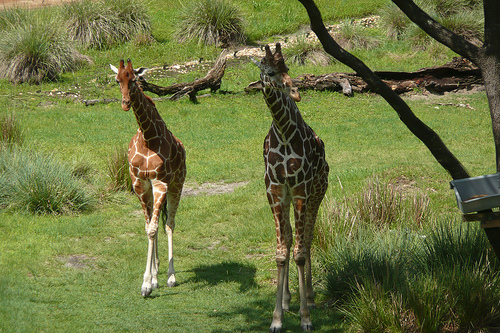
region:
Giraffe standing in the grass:
[90, 53, 213, 303]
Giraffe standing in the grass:
[244, 33, 371, 305]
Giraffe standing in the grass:
[66, 36, 370, 324]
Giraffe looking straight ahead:
[260, 51, 334, 138]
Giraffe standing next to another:
[86, 46, 203, 301]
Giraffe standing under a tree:
[241, 45, 343, 287]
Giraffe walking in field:
[90, 47, 200, 292]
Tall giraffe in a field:
[98, 43, 210, 310]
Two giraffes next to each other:
[90, 54, 347, 274]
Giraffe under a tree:
[239, 34, 371, 294]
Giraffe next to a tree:
[239, 36, 360, 330]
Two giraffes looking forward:
[96, 45, 383, 181]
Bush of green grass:
[13, 116, 90, 228]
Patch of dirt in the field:
[188, 138, 253, 208]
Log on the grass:
[156, 59, 238, 95]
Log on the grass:
[305, 63, 470, 100]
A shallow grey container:
[452, 173, 499, 215]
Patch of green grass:
[8, 291, 126, 328]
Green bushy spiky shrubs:
[8, 24, 90, 81]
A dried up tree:
[163, 43, 240, 103]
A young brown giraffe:
[106, 53, 210, 323]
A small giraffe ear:
[134, 55, 159, 77]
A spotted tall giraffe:
[244, 40, 331, 331]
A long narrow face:
[118, 65, 136, 114]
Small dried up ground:
[198, 168, 253, 198]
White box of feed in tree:
[422, 166, 497, 218]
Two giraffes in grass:
[111, 34, 335, 326]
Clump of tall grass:
[0, 155, 108, 217]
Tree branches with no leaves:
[302, 0, 499, 230]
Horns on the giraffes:
[108, 44, 290, 76]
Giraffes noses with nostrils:
[108, 83, 321, 110]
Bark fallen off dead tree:
[247, 65, 473, 106]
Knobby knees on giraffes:
[266, 245, 315, 284]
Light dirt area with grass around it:
[176, 13, 389, 59]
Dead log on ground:
[146, 48, 233, 103]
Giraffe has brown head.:
[113, 65, 149, 121]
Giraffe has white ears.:
[101, 68, 163, 83]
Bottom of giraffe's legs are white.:
[107, 233, 217, 278]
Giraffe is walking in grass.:
[86, 157, 188, 311]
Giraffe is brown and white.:
[122, 123, 177, 207]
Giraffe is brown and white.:
[256, 96, 324, 207]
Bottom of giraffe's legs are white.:
[250, 255, 337, 322]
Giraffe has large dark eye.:
[253, 60, 277, 85]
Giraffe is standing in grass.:
[256, 250, 341, 324]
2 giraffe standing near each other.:
[58, 83, 388, 286]